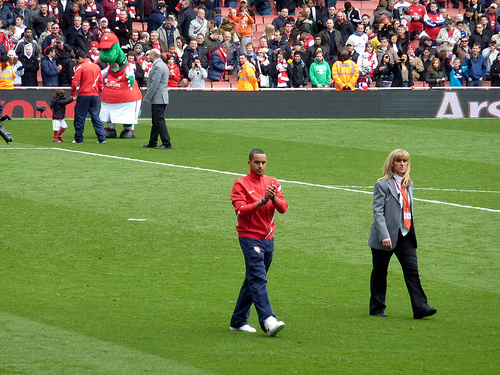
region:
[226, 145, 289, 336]
man in blue pants and red shirt clapping and walking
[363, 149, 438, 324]
woman with blond hair walking with orange tie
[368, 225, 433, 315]
black pants on blond woman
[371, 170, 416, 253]
men's gray blazer on blond woman walking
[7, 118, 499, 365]
green soccer field with white lines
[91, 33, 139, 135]
green mascot wearing red shirt and white shorts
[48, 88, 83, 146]
small child with dark hair and red socks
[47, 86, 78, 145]
small child holding man's hand wearing blue hoodie and white shorts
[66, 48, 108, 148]
dark haired man holding child's hand wearing blue pants and red shirt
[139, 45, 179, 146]
bald man walking near mascot wearing gray blazer and black pants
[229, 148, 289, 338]
Man in red shirt and blue pants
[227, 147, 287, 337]
Man in red shirt is walking and clapping his hands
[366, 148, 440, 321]
Blonde person with red tie and grey jacket is walking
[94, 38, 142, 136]
Green mascot wearing red shirt and white shorts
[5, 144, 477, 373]
Two people walking across football field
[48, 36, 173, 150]
Little child in red boots and white pants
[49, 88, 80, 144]
child wearing black jacket and red boots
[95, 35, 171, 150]
Bald man in grey jacket walks toward green mascot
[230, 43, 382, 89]
two spectators in yellow jackets stand behind the wall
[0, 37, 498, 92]
The crowd of spectators behind the green wall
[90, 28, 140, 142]
Sports team mascot on field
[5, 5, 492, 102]
Spectators preparing to watch soccer match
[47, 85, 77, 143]
Small child on soccer pitch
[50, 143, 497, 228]
White boundary markers on field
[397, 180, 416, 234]
Red tie on man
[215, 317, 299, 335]
White sneakers on man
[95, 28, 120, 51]
Red baseball cap on mascot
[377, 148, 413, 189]
Long blond hair on man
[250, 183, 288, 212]
Clapping hands of a man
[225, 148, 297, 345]
Man walking across soccer pitch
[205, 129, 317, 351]
PErson walking in the field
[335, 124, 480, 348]
Person walking in a field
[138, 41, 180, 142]
Person walking in a field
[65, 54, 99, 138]
Person walking in a field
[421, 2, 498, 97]
Group of fans in the stands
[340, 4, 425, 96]
Group of fans in the stands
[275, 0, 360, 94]
Group of fans in the stands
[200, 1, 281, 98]
Group of fans in the stands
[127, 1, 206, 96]
Group of fans in the stands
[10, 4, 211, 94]
Group of fans in the stands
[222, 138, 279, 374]
Man standing on the field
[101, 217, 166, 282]
Short and green grass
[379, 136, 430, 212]
woman with long blonde hair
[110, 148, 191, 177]
White paint on the field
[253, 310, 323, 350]
Man wearing pair of sneakers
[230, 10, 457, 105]
People in the audience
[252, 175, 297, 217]
Man holding hands together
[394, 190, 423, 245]
Woman wearing a tie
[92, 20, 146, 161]
mascot standing with fans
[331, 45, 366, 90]
man in a yellow jacket